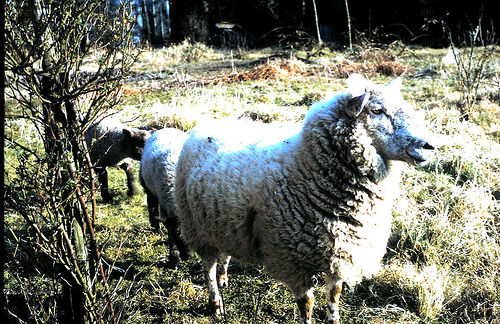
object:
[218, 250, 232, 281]
leg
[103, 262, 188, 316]
waves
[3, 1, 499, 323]
pasture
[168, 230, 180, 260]
leg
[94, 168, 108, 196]
leg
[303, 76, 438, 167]
sheep head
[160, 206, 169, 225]
leg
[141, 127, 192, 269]
lamb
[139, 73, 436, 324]
lamb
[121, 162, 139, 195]
leg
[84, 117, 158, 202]
cat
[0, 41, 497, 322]
grass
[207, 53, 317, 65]
log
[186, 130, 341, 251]
wool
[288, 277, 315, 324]
legs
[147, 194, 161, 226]
leg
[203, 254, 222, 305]
leg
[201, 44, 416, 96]
moss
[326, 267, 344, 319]
leg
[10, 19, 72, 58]
branches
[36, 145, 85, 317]
branches